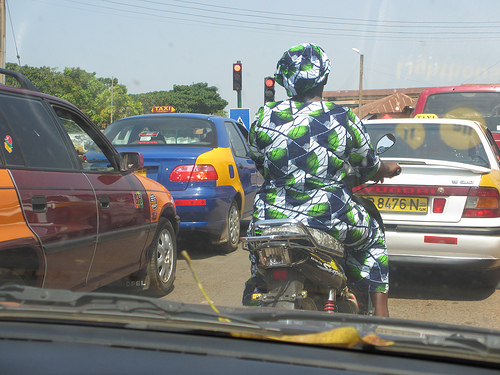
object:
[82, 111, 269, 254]
car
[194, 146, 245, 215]
spots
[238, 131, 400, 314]
moped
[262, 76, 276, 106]
light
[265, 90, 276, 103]
semaphore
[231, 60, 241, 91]
lights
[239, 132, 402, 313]
motorbike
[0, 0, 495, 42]
sky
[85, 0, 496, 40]
wires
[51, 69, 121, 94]
leaves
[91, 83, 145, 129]
trees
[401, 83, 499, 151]
truck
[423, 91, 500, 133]
window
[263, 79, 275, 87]
circles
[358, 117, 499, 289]
cab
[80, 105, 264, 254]
vehicle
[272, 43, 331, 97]
cloth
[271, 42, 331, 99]
head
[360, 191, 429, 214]
plate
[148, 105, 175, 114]
sign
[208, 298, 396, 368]
leaf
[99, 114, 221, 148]
windshield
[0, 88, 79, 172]
window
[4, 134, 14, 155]
decal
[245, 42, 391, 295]
outfit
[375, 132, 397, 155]
mirror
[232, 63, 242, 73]
signals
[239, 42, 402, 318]
person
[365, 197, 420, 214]
numbers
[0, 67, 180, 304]
cars